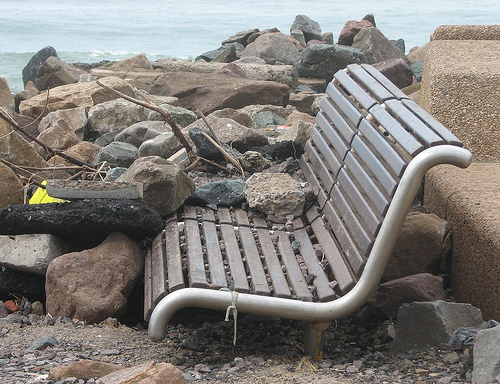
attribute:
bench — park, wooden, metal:
[135, 28, 493, 368]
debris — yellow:
[23, 167, 83, 214]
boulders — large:
[120, 21, 378, 111]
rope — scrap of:
[224, 290, 239, 343]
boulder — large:
[154, 67, 296, 128]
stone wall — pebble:
[399, 19, 499, 331]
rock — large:
[240, 170, 305, 222]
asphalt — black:
[1, 197, 165, 242]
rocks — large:
[15, 10, 435, 216]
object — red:
[0, 272, 36, 323]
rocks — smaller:
[280, 219, 340, 303]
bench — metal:
[122, 52, 469, 367]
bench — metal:
[142, 57, 474, 352]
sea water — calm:
[0, 2, 495, 64]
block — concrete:
[417, 23, 484, 306]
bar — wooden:
[177, 216, 213, 289]